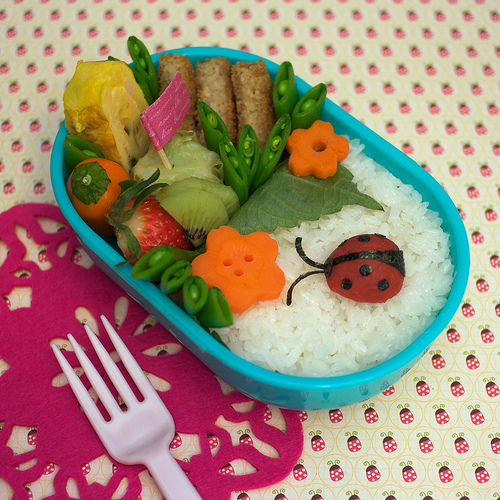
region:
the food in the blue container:
[45, 35, 453, 377]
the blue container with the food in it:
[47, 32, 468, 410]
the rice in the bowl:
[208, 134, 456, 383]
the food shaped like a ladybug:
[286, 232, 406, 303]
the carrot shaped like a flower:
[190, 225, 286, 311]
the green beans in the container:
[59, 32, 328, 328]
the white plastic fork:
[50, 312, 203, 498]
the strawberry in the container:
[110, 177, 191, 264]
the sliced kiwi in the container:
[155, 180, 240, 246]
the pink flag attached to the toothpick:
[138, 71, 190, 170]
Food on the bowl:
[45, 43, 432, 375]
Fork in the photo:
[22, 309, 201, 494]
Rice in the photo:
[270, 287, 358, 359]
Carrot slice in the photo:
[192, 215, 277, 309]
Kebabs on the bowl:
[180, 52, 282, 148]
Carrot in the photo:
[77, 160, 127, 216]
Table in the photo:
[346, 424, 447, 496]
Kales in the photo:
[257, 164, 343, 231]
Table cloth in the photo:
[320, 37, 426, 109]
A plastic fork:
[56, 338, 221, 498]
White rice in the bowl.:
[271, 193, 413, 331]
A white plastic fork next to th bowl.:
[56, 304, 184, 469]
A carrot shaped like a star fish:
[193, 210, 287, 312]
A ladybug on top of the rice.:
[288, 219, 421, 315]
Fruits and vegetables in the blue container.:
[104, 105, 235, 259]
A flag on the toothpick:
[132, 74, 197, 174]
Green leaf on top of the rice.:
[247, 160, 377, 220]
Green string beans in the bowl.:
[203, 103, 282, 180]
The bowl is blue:
[162, 328, 430, 416]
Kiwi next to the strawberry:
[159, 182, 229, 232]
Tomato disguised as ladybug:
[275, 220, 415, 310]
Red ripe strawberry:
[105, 185, 195, 270]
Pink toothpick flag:
[135, 65, 205, 180]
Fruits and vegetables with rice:
[30, 30, 470, 415]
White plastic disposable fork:
[45, 305, 210, 490]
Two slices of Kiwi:
[150, 170, 235, 245]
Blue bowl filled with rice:
[45, 35, 475, 410]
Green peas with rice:
[40, 25, 470, 420]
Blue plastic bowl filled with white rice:
[45, 40, 470, 415]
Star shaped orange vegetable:
[282, 108, 350, 185]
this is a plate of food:
[27, 12, 492, 413]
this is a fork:
[51, 331, 198, 486]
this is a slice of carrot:
[165, 212, 306, 317]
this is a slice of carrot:
[282, 115, 357, 199]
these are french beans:
[135, 242, 252, 350]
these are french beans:
[195, 103, 255, 195]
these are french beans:
[271, 48, 326, 130]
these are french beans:
[54, 128, 114, 180]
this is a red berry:
[100, 183, 192, 287]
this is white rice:
[194, 126, 456, 387]